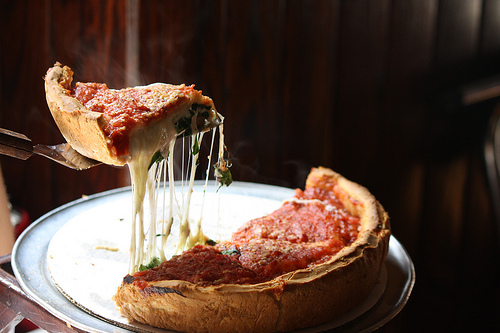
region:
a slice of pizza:
[45, 57, 215, 164]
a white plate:
[20, 182, 395, 327]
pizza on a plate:
[135, 182, 395, 322]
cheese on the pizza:
[120, 156, 215, 246]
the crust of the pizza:
[46, 100, 98, 150]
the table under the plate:
[1, 285, 51, 330]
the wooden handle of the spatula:
[2, 126, 32, 156]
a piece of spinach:
[210, 158, 237, 188]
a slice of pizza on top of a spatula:
[39, 54, 266, 141]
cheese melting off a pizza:
[111, 122, 221, 233]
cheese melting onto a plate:
[90, 96, 232, 261]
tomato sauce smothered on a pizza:
[215, 217, 339, 281]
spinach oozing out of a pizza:
[165, 112, 245, 188]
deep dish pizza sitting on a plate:
[69, 181, 389, 332]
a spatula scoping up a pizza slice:
[5, 102, 98, 183]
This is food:
[33, 54, 428, 331]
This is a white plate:
[8, 153, 438, 331]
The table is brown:
[248, 26, 458, 148]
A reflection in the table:
[336, 48, 498, 213]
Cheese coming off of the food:
[43, 57, 241, 251]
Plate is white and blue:
[13, 167, 420, 332]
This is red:
[40, 53, 235, 181]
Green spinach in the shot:
[142, 79, 252, 195]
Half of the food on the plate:
[89, 147, 426, 332]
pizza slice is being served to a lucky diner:
[3, 54, 420, 331]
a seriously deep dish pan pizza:
[112, 155, 392, 330]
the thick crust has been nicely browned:
[110, 265, 365, 326]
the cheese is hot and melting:
[120, 132, 215, 263]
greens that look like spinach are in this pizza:
[170, 100, 236, 190]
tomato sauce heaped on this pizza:
[126, 185, 361, 280]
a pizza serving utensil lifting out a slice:
[0, 91, 220, 176]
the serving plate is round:
[10, 170, 420, 330]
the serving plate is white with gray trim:
[10, 171, 420, 328]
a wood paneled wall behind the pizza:
[145, 5, 483, 268]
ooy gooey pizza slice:
[37, 53, 238, 170]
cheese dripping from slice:
[120, 117, 229, 266]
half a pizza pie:
[136, 153, 380, 330]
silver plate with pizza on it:
[12, 169, 422, 331]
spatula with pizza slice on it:
[0, 106, 220, 176]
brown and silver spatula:
[2, 124, 89, 181]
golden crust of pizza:
[334, 157, 388, 316]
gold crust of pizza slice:
[31, 59, 113, 169]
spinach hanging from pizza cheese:
[177, 104, 237, 194]